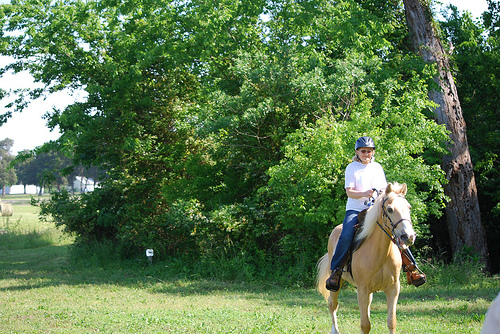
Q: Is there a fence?
A: No, there are no fences.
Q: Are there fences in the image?
A: No, there are no fences.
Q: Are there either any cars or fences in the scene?
A: No, there are no fences or cars.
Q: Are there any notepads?
A: No, there are no notepads.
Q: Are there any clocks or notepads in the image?
A: No, there are no notepads or clocks.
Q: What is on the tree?
A: The leaves are on the tree.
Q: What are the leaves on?
A: The leaves are on the tree.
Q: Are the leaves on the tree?
A: Yes, the leaves are on the tree.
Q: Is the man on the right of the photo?
A: Yes, the man is on the right of the image.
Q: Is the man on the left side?
A: No, the man is on the right of the image.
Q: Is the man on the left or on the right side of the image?
A: The man is on the right of the image.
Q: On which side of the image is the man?
A: The man is on the right of the image.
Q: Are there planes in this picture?
A: No, there are no planes.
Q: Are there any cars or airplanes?
A: No, there are no airplanes or cars.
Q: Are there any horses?
A: Yes, there is a horse.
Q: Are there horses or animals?
A: Yes, there is a horse.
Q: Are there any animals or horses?
A: Yes, there is a horse.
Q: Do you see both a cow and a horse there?
A: No, there is a horse but no cows.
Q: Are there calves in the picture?
A: No, there are no calves.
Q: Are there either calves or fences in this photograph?
A: No, there are no calves or fences.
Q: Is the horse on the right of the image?
A: Yes, the horse is on the right of the image.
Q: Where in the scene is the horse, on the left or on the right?
A: The horse is on the right of the image.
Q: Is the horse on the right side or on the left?
A: The horse is on the right of the image.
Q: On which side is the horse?
A: The horse is on the right of the image.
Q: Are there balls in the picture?
A: No, there are no balls.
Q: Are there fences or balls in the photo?
A: No, there are no balls or fences.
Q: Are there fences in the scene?
A: No, there are no fences.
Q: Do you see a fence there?
A: No, there are no fences.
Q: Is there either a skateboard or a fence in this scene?
A: No, there are no fences or skateboards.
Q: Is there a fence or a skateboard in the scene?
A: No, there are no fences or skateboards.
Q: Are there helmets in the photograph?
A: Yes, there is a helmet.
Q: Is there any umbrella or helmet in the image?
A: Yes, there is a helmet.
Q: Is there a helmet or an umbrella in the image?
A: Yes, there is a helmet.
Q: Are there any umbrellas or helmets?
A: Yes, there is a helmet.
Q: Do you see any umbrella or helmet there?
A: Yes, there is a helmet.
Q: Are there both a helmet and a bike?
A: No, there is a helmet but no bikes.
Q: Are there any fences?
A: No, there are no fences.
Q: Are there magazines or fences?
A: No, there are no fences or magazines.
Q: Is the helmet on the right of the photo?
A: Yes, the helmet is on the right of the image.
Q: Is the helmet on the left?
A: No, the helmet is on the right of the image.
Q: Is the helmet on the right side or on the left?
A: The helmet is on the right of the image.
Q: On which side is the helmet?
A: The helmet is on the right of the image.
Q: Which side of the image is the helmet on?
A: The helmet is on the right of the image.